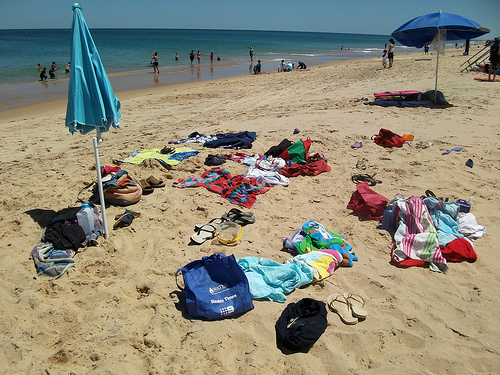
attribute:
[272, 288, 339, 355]
fanny pack — black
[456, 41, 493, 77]
stairs — wooden, angling down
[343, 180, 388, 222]
bag — red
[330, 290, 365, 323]
shoes — pair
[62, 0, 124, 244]
beach umbrellla — closed, light blue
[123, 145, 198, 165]
beach towel — yellow, blue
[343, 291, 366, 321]
flip flop — pair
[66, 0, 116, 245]
umbrella — blue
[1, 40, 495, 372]
sand — tan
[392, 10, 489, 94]
umbrella — blue, dark blue, opened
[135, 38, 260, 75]
people — walking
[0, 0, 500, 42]
sky — blue, clear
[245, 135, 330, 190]
belongings — personal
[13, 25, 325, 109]
shore — wet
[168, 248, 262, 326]
bag — blue 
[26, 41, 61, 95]
people — playing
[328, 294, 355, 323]
flip flop — pair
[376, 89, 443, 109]
lounge — reclining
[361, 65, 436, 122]
chair — horizontal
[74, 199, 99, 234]
water jug — plastic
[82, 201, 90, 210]
cap — blue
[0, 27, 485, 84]
water — blue